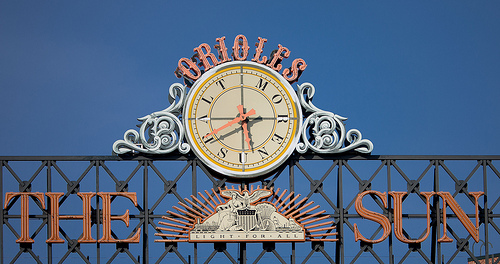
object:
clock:
[173, 56, 308, 183]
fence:
[0, 151, 500, 264]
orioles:
[170, 27, 310, 84]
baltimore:
[0, 0, 500, 264]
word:
[1, 190, 142, 245]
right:
[474, 4, 498, 256]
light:
[3, 1, 499, 264]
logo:
[151, 179, 349, 247]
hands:
[201, 108, 258, 141]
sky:
[3, 3, 500, 155]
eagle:
[219, 187, 274, 206]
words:
[346, 188, 487, 246]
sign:
[186, 187, 307, 243]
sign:
[109, 34, 380, 179]